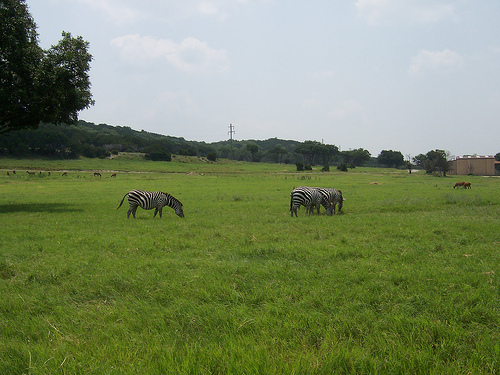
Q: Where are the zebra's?
A: Grazing on grasses.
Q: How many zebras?
A: At least 3.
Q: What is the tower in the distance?
A: A power line.